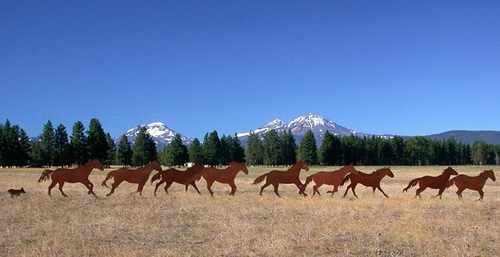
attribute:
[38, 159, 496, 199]
horses — running, brown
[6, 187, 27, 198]
dog — brown, running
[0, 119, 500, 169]
trees — green, big, pine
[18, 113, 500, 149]
mountains — white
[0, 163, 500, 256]
grass — dry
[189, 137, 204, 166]
tree — small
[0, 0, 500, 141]
sky — blue, clear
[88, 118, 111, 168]
tree — large